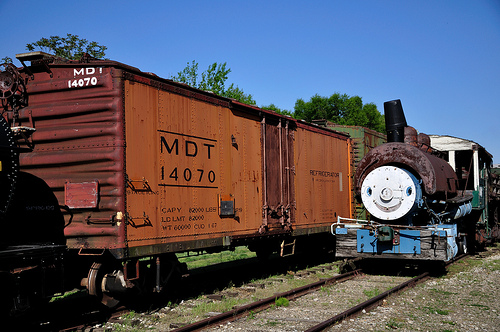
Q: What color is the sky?
A: Blue.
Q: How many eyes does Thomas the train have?
A: Two.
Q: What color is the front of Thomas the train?
A: Blue.